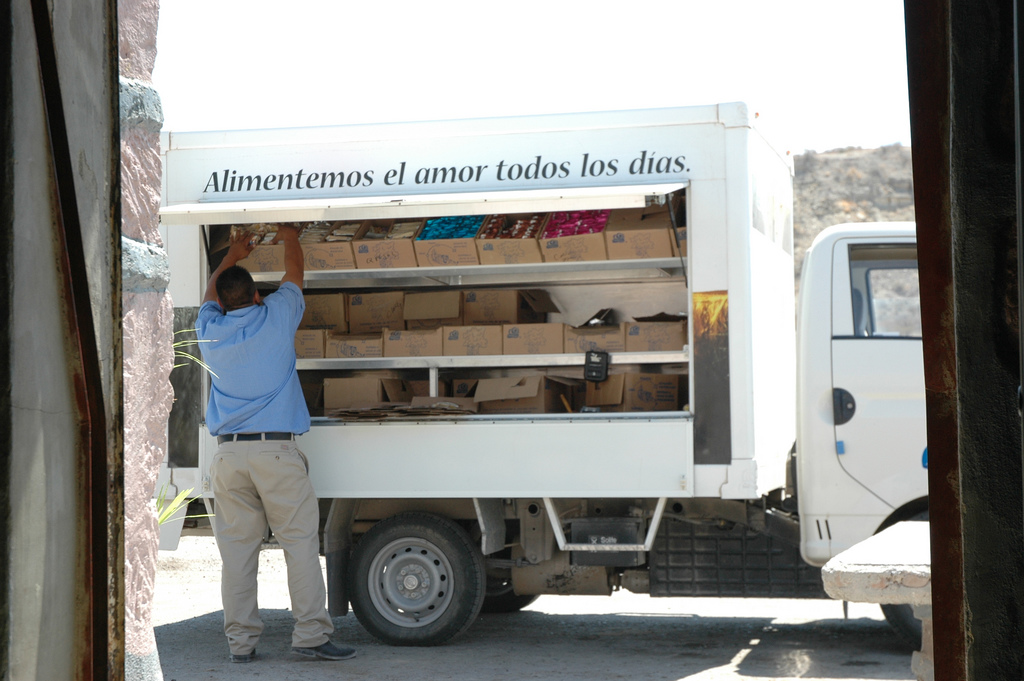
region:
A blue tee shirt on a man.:
[193, 278, 312, 434]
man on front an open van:
[146, 80, 949, 670]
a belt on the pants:
[206, 426, 301, 445]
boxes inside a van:
[271, 169, 705, 449]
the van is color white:
[150, 73, 945, 650]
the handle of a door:
[827, 377, 860, 435]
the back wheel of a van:
[341, 518, 495, 662]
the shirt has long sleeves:
[183, 276, 319, 449]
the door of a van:
[813, 227, 930, 529]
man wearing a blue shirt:
[182, 240, 361, 678]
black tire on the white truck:
[351, 508, 488, 658]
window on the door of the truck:
[842, 241, 923, 340]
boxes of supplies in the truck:
[307, 230, 694, 272]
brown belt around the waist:
[219, 424, 297, 448]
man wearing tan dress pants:
[194, 255, 350, 677]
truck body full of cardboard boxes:
[160, 123, 778, 488]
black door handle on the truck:
[823, 388, 858, 428]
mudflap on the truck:
[320, 503, 353, 622]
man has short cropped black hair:
[193, 234, 367, 678]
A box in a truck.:
[600, 204, 677, 259]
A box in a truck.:
[539, 204, 609, 258]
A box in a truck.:
[471, 213, 542, 259]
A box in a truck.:
[410, 217, 475, 265]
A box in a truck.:
[350, 225, 426, 264]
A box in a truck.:
[290, 222, 352, 270]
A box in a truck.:
[226, 223, 302, 265]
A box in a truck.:
[505, 320, 560, 347]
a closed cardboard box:
[440, 318, 494, 350]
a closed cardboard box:
[383, 315, 457, 361]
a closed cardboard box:
[349, 282, 401, 330]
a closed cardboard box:
[401, 283, 458, 332]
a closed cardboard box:
[462, 279, 535, 331]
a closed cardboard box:
[311, 371, 391, 411]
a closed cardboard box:
[475, 365, 545, 419]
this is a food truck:
[87, 107, 881, 573]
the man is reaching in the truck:
[175, 243, 391, 608]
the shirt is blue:
[163, 259, 294, 377]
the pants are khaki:
[171, 447, 374, 629]